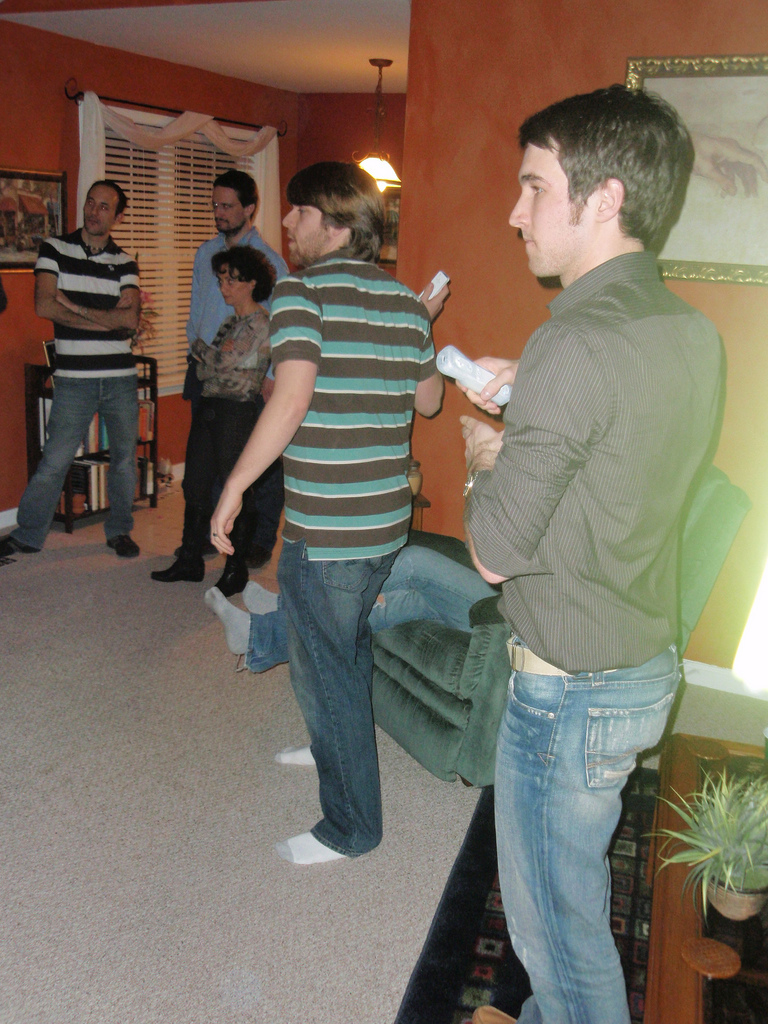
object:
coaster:
[681, 936, 741, 979]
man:
[210, 161, 450, 867]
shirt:
[269, 250, 437, 560]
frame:
[625, 54, 764, 286]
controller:
[436, 345, 513, 406]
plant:
[642, 766, 768, 927]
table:
[644, 733, 768, 1024]